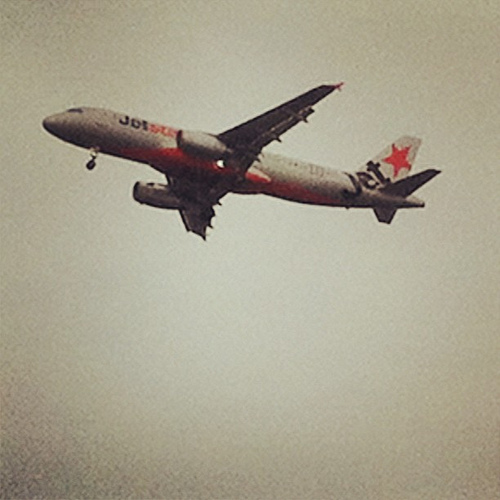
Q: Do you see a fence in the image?
A: No, there are no fences.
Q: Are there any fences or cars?
A: No, there are no fences or cars.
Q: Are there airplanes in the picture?
A: Yes, there is an airplane.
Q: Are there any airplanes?
A: Yes, there is an airplane.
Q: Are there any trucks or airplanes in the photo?
A: Yes, there is an airplane.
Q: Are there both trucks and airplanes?
A: No, there is an airplane but no trucks.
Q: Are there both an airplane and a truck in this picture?
A: No, there is an airplane but no trucks.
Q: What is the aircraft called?
A: The aircraft is an airplane.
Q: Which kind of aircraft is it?
A: The aircraft is an airplane.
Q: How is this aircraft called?
A: This is an airplane.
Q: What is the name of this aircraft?
A: This is an airplane.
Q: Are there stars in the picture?
A: Yes, there is a star.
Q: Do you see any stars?
A: Yes, there is a star.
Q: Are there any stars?
A: Yes, there is a star.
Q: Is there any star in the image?
A: Yes, there is a star.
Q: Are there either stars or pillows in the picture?
A: Yes, there is a star.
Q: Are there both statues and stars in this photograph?
A: No, there is a star but no statues.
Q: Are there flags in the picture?
A: No, there are no flags.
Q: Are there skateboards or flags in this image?
A: No, there are no flags or skateboards.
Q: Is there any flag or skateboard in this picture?
A: No, there are no flags or skateboards.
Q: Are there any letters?
A: Yes, there are letters.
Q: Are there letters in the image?
A: Yes, there are letters.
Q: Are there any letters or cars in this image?
A: Yes, there are letters.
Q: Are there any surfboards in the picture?
A: No, there are no surfboards.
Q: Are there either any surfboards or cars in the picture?
A: No, there are no surfboards or cars.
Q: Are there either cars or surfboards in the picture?
A: No, there are no surfboards or cars.